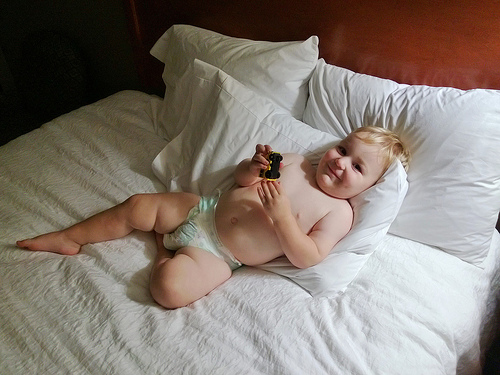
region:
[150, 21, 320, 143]
White bed pillow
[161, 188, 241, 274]
Baby's wet diaper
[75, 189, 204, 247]
Chubby leg of a baby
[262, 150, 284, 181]
Child's yellow and black toy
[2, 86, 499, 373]
Bed with a white coverlet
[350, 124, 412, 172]
Baby's blonde hair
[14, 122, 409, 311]
Cute, chubby baby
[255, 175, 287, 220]
Baby's chubby fingers and hand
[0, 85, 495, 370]
Chubby baby on a white bed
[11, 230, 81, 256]
Chubby baby's foot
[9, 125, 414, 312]
a chubby baby in bed.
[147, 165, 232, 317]
a baby in a diaper.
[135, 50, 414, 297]
a baby on a white pillow.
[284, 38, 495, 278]
a large white pillow.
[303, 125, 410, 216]
a baby with blonde hair.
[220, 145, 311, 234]
a baby holding an object.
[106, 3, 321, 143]
a white pillow on a bed.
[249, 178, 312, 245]
a chubby babies left hand.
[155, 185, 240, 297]
a baby in a diaper on a bed.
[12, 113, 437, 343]
the toddler is on the bed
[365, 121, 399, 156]
the hair is blonde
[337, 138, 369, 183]
the toddler has eyes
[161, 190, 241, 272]
the toddler is wearing a diaper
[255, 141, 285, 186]
the toddler is holding a truck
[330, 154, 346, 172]
the toddler has a nose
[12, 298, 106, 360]
the blanket is white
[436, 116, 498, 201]
the pillow case is white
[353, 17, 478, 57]
the headboard is brown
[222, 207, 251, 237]
the toddler has a belly button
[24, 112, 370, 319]
baby laying on the bed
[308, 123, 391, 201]
head of the baby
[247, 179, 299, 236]
hand of the baby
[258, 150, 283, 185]
car in baby's hand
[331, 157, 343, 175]
nose of the baby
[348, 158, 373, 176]
eye of the baby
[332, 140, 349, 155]
eye of hte baby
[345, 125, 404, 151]
hair of the baby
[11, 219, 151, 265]
leg of the baby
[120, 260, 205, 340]
knee of the baby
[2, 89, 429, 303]
a baby in the bed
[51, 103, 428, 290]
a baby in bed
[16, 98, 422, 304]
a large baby in bed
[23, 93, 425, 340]
a large baby in the bed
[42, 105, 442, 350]
a bed with a baby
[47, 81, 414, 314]
a blonde baby in bed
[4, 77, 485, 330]
a bed with a blonde baby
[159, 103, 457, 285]
a baby holding a toy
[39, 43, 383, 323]
a baby wearing a diaper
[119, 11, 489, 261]
a bed with three pillows